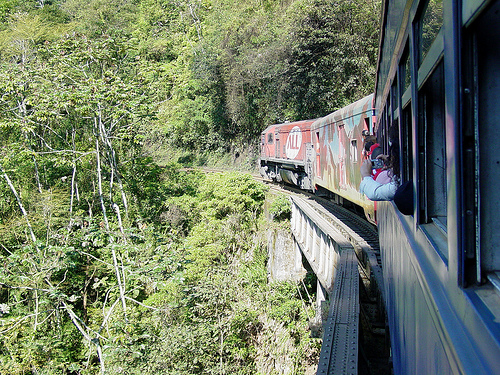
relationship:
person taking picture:
[353, 120, 406, 208] [366, 157, 387, 168]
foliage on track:
[228, 198, 286, 213] [315, 194, 350, 229]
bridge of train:
[308, 249, 341, 319] [260, 114, 311, 192]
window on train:
[427, 121, 441, 187] [260, 114, 311, 192]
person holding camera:
[353, 120, 406, 208] [362, 155, 379, 174]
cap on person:
[374, 146, 386, 153] [353, 120, 406, 208]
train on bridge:
[260, 114, 311, 192] [308, 249, 341, 319]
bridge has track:
[308, 249, 341, 319] [315, 194, 350, 229]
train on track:
[260, 114, 311, 192] [315, 194, 350, 229]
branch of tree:
[63, 59, 79, 81] [305, 30, 349, 96]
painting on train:
[340, 106, 355, 125] [260, 114, 311, 192]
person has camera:
[353, 120, 406, 208] [362, 155, 379, 174]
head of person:
[375, 148, 390, 163] [353, 120, 406, 208]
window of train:
[427, 121, 441, 187] [260, 114, 311, 192]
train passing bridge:
[260, 114, 311, 192] [308, 249, 341, 319]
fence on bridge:
[213, 177, 227, 195] [308, 249, 341, 319]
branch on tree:
[63, 59, 79, 81] [305, 30, 349, 96]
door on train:
[449, 247, 457, 280] [260, 114, 311, 192]